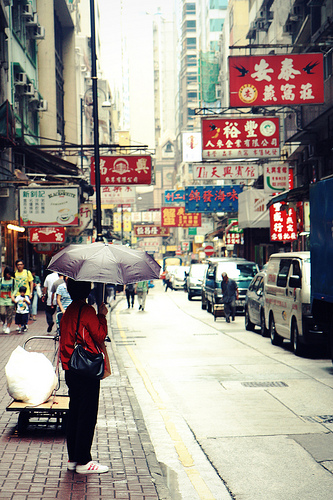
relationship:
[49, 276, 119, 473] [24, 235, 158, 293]
woman holding umbrella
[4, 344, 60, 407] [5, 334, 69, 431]
bag on cart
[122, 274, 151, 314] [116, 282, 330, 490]
people walking down street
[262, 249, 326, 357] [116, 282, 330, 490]
van parked on street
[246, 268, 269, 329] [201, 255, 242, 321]
car parked between van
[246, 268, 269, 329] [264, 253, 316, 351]
car parked between van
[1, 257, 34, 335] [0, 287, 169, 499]
family walking on sidewalk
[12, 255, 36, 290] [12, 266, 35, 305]
person wearing shirt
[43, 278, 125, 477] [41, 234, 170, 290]
person holding umbrella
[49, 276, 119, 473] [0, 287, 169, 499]
woman on sidewalk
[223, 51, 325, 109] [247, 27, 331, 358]
sign on a building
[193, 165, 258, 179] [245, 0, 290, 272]
sign on a building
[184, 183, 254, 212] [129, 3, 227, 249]
sign on a building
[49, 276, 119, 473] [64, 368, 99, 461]
woman wearing pants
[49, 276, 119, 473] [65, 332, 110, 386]
woman carrying bag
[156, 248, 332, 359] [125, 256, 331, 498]
cars on street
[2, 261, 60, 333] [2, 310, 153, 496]
people walking on sidewalk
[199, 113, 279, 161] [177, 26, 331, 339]
sign on buildings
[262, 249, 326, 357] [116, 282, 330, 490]
van on street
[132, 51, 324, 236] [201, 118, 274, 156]
signs written in chinese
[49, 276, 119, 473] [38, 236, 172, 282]
woman has umbrella